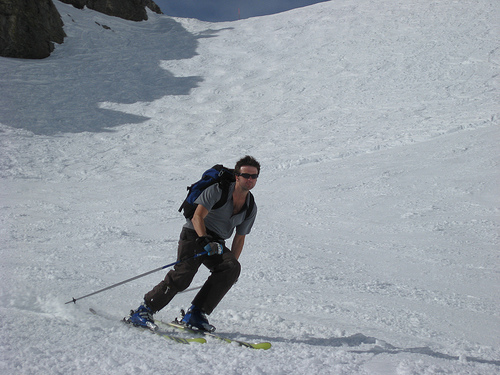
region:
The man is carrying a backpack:
[156, 150, 266, 241]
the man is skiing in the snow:
[48, 126, 295, 326]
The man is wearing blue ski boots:
[114, 305, 226, 341]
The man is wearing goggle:
[226, 153, 269, 200]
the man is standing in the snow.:
[148, 127, 276, 344]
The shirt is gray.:
[194, 180, 299, 261]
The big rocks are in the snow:
[28, 10, 135, 70]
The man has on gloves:
[167, 222, 256, 291]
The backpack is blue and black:
[151, 151, 262, 243]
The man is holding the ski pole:
[66, 236, 242, 307]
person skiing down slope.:
[30, 67, 437, 365]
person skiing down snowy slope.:
[50, 70, 431, 361]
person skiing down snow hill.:
[31, 87, 407, 362]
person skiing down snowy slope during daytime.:
[55, 90, 415, 356]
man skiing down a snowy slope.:
[70, 91, 341, 347]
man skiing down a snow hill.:
[55, 86, 392, 366]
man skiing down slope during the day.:
[71, 105, 311, 355]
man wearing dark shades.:
[206, 131, 281, 217]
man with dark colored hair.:
[210, 140, 275, 215]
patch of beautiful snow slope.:
[46, 20, 441, 125]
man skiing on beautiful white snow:
[75, 141, 301, 343]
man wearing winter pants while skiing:
[105, 241, 297, 335]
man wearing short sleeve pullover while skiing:
[153, 190, 303, 254]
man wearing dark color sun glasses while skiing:
[225, 148, 296, 208]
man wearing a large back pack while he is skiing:
[125, 143, 290, 267]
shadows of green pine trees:
[15, 35, 250, 167]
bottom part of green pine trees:
[0, 7, 201, 55]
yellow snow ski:
[63, 313, 283, 369]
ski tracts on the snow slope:
[20, 271, 449, 359]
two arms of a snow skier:
[130, 193, 289, 280]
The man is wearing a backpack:
[181, 157, 225, 222]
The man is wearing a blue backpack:
[159, 159, 246, 219]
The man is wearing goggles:
[221, 161, 274, 196]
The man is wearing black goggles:
[235, 162, 267, 207]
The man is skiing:
[55, 232, 254, 310]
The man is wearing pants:
[148, 217, 263, 332]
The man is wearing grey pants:
[149, 222, 261, 334]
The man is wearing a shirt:
[177, 184, 257, 254]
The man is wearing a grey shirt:
[175, 157, 260, 256]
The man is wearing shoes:
[108, 282, 257, 373]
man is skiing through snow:
[162, 150, 287, 342]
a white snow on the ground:
[322, 309, 436, 370]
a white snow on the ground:
[195, 338, 259, 370]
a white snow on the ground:
[64, 185, 129, 369]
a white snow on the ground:
[245, 58, 422, 135]